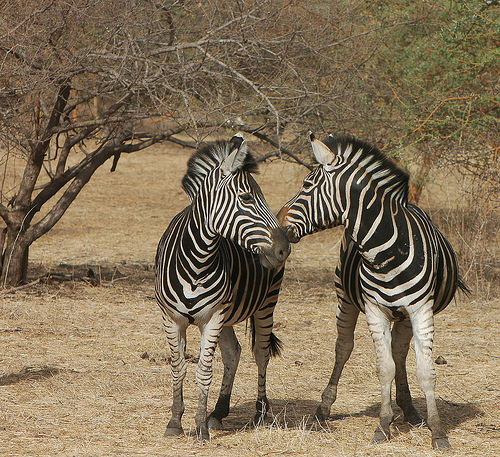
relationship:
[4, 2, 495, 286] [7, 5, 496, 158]
tree without leaves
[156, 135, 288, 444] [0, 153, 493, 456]
zebra on ground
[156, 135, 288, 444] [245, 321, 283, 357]
zebra has tail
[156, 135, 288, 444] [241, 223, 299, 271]
zebra has nose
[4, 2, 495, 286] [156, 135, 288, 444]
tree next to zebra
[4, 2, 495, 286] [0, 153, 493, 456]
tree on ground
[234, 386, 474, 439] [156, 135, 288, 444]
shadows of zebra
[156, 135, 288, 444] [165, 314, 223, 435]
zebra has leg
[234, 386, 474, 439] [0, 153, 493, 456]
shadows on ground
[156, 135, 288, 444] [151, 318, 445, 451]
zebra has legs